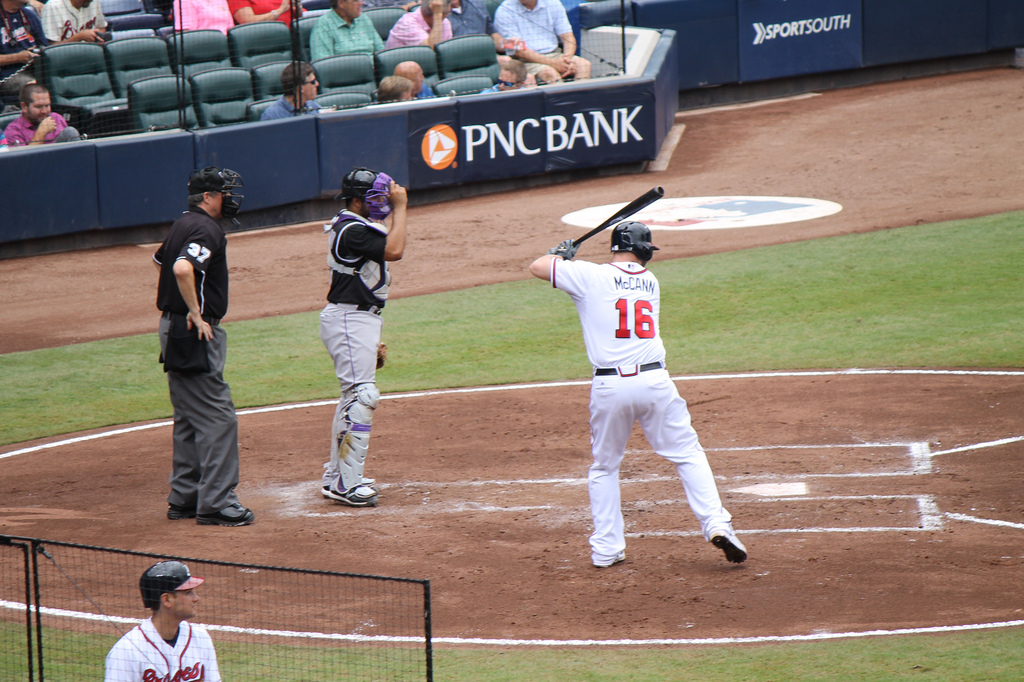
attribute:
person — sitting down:
[382, 59, 465, 94]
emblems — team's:
[540, 171, 849, 252]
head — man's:
[115, 536, 209, 619]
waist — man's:
[586, 338, 677, 393]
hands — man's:
[166, 305, 216, 345]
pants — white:
[544, 350, 759, 562]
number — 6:
[635, 292, 661, 347]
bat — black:
[547, 180, 682, 258]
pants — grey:
[309, 290, 402, 507]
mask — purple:
[359, 169, 392, 222]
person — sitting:
[398, 59, 440, 103]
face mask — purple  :
[357, 175, 407, 215]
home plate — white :
[741, 482, 817, 513]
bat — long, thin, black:
[611, 189, 664, 218]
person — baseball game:
[248, 39, 326, 126]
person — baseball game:
[265, 11, 430, 91]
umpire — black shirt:
[157, 150, 283, 513]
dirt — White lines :
[851, 377, 968, 574]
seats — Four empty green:
[24, 26, 342, 115]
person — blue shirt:
[501, 9, 599, 94]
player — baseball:
[535, 165, 806, 596]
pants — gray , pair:
[134, 316, 279, 537]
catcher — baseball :
[326, 154, 443, 498]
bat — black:
[566, 190, 666, 262]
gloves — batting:
[532, 251, 589, 280]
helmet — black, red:
[132, 553, 217, 614]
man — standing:
[517, 247, 744, 548]